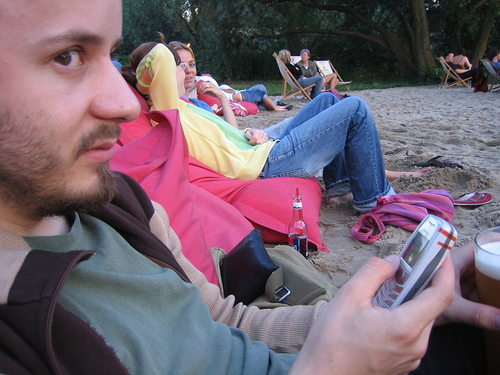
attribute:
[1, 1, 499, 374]
people — sitting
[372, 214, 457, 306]
cell phone — silver, grey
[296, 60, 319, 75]
shirt — green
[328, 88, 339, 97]
flip flops — pink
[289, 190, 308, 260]
bottle — glass, half full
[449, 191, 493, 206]
sandal — pink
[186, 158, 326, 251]
pillow — pink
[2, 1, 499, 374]
man — looking, texting, starring, sitting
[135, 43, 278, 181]
shirt — yellow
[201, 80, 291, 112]
person — laying down, sitting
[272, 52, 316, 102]
chairs — wooden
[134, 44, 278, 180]
sweater — yellow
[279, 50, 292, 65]
hair — blonde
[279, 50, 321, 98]
woman — sitting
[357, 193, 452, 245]
clothing — pink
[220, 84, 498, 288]
ground — sandy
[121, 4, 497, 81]
forest — green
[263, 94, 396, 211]
jeans — blue